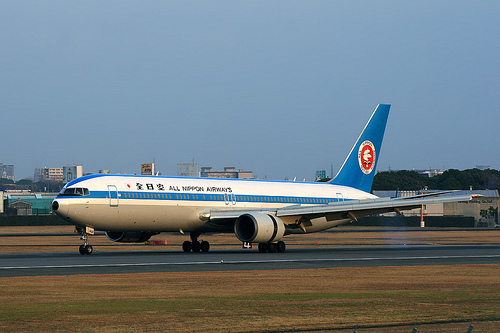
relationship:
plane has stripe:
[48, 101, 475, 257] [88, 190, 360, 206]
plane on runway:
[48, 101, 475, 257] [2, 244, 500, 273]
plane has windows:
[48, 101, 475, 257] [121, 191, 127, 201]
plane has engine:
[48, 101, 475, 257] [231, 213, 285, 248]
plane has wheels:
[48, 101, 475, 257] [78, 245, 95, 255]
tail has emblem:
[325, 102, 397, 194] [357, 137, 376, 176]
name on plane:
[134, 183, 233, 193] [48, 101, 475, 257]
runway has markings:
[2, 244, 500, 273] [0, 255, 499, 271]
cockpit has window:
[54, 173, 100, 224] [58, 187, 89, 199]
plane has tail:
[48, 101, 475, 257] [325, 102, 397, 194]